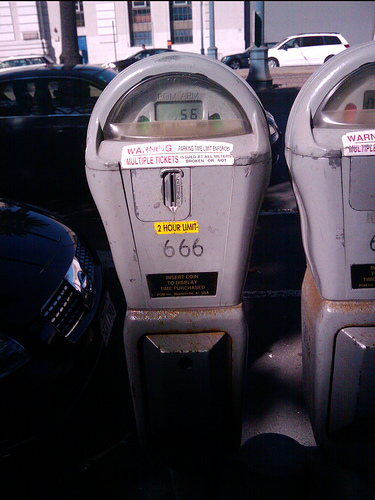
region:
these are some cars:
[107, 32, 349, 63]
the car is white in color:
[303, 47, 319, 62]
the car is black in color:
[237, 55, 243, 64]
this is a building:
[72, 1, 255, 53]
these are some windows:
[131, 3, 196, 42]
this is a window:
[50, 86, 81, 105]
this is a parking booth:
[73, 31, 274, 361]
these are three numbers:
[155, 232, 211, 257]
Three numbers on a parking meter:
[163, 239, 203, 258]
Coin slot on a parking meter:
[166, 175, 178, 208]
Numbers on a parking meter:
[154, 100, 203, 121]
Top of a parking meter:
[84, 50, 274, 313]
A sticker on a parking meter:
[154, 220, 199, 232]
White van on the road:
[265, 31, 348, 65]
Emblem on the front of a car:
[77, 268, 92, 292]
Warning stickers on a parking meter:
[119, 143, 236, 167]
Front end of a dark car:
[1, 197, 117, 405]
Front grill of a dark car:
[40, 240, 96, 343]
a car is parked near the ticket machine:
[9, 203, 111, 387]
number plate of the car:
[88, 288, 121, 343]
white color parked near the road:
[247, 21, 350, 61]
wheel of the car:
[264, 54, 279, 69]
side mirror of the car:
[279, 44, 292, 53]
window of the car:
[278, 36, 343, 46]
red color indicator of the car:
[342, 41, 352, 48]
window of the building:
[126, 3, 202, 48]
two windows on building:
[88, 3, 243, 64]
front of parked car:
[1, 199, 115, 416]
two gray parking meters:
[84, 41, 372, 499]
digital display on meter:
[156, 98, 202, 118]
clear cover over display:
[110, 75, 249, 137]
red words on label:
[120, 140, 234, 168]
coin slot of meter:
[162, 169, 181, 213]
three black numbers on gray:
[163, 237, 203, 257]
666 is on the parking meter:
[156, 235, 212, 259]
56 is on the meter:
[177, 105, 204, 122]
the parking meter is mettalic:
[87, 59, 272, 438]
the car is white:
[273, 27, 344, 59]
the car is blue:
[10, 204, 118, 404]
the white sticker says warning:
[338, 128, 373, 158]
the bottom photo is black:
[6, 435, 371, 483]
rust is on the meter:
[303, 283, 345, 313]